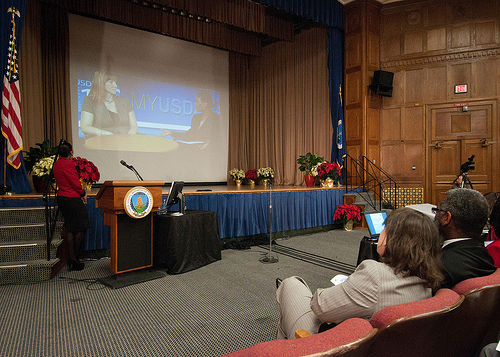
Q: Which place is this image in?
A: It is at the stage.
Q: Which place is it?
A: It is a stage.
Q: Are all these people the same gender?
A: No, they are both male and female.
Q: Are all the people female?
A: No, they are both male and female.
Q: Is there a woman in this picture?
A: Yes, there is a woman.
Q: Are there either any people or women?
A: Yes, there is a woman.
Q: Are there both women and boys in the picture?
A: No, there is a woman but no boys.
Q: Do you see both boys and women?
A: No, there is a woman but no boys.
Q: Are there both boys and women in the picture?
A: No, there is a woman but no boys.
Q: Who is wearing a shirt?
A: The woman is wearing a shirt.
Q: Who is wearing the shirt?
A: The woman is wearing a shirt.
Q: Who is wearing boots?
A: The woman is wearing boots.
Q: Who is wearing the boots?
A: The woman is wearing boots.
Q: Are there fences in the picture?
A: No, there are no fences.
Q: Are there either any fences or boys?
A: No, there are no fences or boys.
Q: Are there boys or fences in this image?
A: No, there are no fences or boys.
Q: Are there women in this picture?
A: Yes, there is a woman.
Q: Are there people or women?
A: Yes, there is a woman.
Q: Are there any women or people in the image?
A: Yes, there is a woman.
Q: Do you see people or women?
A: Yes, there is a woman.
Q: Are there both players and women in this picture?
A: No, there is a woman but no players.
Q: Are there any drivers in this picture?
A: No, there are no drivers.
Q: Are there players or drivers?
A: No, there are no drivers or players.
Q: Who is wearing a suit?
A: The woman is wearing a suit.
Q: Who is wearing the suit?
A: The woman is wearing a suit.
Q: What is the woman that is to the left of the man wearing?
A: The woman is wearing a suit.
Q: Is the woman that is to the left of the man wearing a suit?
A: Yes, the woman is wearing a suit.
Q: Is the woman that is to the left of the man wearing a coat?
A: No, the woman is wearing a suit.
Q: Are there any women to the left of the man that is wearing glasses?
A: Yes, there is a woman to the left of the man.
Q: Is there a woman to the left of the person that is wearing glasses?
A: Yes, there is a woman to the left of the man.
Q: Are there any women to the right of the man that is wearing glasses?
A: No, the woman is to the left of the man.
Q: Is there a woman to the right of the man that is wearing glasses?
A: No, the woman is to the left of the man.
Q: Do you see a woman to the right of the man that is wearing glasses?
A: No, the woman is to the left of the man.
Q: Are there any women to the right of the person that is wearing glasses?
A: No, the woman is to the left of the man.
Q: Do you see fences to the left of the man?
A: No, there is a woman to the left of the man.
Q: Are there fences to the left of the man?
A: No, there is a woman to the left of the man.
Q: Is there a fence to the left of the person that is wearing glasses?
A: No, there is a woman to the left of the man.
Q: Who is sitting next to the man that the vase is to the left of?
A: The woman is sitting next to the man.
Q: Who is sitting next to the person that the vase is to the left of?
A: The woman is sitting next to the man.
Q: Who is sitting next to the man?
A: The woman is sitting next to the man.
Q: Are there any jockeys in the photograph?
A: No, there are no jockeys.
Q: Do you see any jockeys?
A: No, there are no jockeys.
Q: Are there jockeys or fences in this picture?
A: No, there are no jockeys or fences.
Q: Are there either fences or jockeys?
A: No, there are no jockeys or fences.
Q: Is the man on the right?
A: Yes, the man is on the right of the image.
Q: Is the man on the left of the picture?
A: No, the man is on the right of the image.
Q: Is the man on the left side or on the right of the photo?
A: The man is on the right of the image.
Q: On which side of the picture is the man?
A: The man is on the right of the image.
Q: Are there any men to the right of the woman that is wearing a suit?
A: Yes, there is a man to the right of the woman.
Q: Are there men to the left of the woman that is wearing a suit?
A: No, the man is to the right of the woman.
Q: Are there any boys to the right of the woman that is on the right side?
A: No, there is a man to the right of the woman.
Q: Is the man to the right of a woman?
A: Yes, the man is to the right of a woman.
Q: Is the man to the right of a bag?
A: No, the man is to the right of a woman.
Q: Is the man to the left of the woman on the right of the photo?
A: No, the man is to the right of the woman.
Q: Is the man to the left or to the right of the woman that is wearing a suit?
A: The man is to the right of the woman.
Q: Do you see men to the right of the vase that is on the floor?
A: Yes, there is a man to the right of the vase.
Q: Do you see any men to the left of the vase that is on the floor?
A: No, the man is to the right of the vase.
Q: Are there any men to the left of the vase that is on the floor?
A: No, the man is to the right of the vase.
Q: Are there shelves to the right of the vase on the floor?
A: No, there is a man to the right of the vase.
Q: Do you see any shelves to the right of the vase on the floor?
A: No, there is a man to the right of the vase.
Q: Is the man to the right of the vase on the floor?
A: Yes, the man is to the right of the vase.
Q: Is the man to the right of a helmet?
A: No, the man is to the right of the vase.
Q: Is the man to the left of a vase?
A: No, the man is to the right of a vase.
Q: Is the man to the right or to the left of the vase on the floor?
A: The man is to the right of the vase.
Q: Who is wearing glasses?
A: The man is wearing glasses.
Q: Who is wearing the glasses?
A: The man is wearing glasses.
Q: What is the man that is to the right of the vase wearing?
A: The man is wearing glasses.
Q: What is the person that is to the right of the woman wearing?
A: The man is wearing glasses.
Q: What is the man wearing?
A: The man is wearing glasses.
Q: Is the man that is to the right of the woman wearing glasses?
A: Yes, the man is wearing glasses.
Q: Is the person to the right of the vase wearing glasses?
A: Yes, the man is wearing glasses.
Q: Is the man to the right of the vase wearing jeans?
A: No, the man is wearing glasses.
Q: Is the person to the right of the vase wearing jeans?
A: No, the man is wearing glasses.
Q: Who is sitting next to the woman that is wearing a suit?
A: The man is sitting next to the woman.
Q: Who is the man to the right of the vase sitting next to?
A: The man is sitting next to the woman.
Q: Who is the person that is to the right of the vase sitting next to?
A: The man is sitting next to the woman.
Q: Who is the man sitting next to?
A: The man is sitting next to the woman.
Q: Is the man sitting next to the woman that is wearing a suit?
A: Yes, the man is sitting next to the woman.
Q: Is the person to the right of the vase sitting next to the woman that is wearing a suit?
A: Yes, the man is sitting next to the woman.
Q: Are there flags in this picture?
A: Yes, there is a flag.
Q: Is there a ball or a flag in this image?
A: Yes, there is a flag.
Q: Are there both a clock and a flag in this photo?
A: No, there is a flag but no clocks.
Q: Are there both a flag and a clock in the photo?
A: No, there is a flag but no clocks.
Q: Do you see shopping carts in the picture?
A: No, there are no shopping carts.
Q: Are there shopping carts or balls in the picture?
A: No, there are no shopping carts or balls.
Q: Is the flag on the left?
A: Yes, the flag is on the left of the image.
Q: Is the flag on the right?
A: No, the flag is on the left of the image.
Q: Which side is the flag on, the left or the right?
A: The flag is on the left of the image.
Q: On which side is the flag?
A: The flag is on the left of the image.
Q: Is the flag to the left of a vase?
A: Yes, the flag is to the left of a vase.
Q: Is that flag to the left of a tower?
A: No, the flag is to the left of a vase.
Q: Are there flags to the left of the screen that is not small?
A: Yes, there is a flag to the left of the screen.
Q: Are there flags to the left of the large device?
A: Yes, there is a flag to the left of the screen.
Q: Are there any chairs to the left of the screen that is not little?
A: No, there is a flag to the left of the screen.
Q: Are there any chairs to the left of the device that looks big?
A: No, there is a flag to the left of the screen.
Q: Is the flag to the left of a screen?
A: Yes, the flag is to the left of a screen.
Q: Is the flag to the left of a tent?
A: No, the flag is to the left of a screen.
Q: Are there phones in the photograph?
A: No, there are no phones.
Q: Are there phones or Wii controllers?
A: No, there are no phones or Wii controllers.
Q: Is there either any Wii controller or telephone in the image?
A: No, there are no phones or Wii controllers.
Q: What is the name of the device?
A: The device is a screen.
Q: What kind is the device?
A: The device is a screen.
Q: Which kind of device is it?
A: The device is a screen.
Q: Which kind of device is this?
A: This is a screen.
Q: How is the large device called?
A: The device is a screen.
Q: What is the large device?
A: The device is a screen.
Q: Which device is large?
A: The device is a screen.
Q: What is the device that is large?
A: The device is a screen.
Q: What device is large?
A: The device is a screen.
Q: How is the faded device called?
A: The device is a screen.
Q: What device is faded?
A: The device is a screen.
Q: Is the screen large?
A: Yes, the screen is large.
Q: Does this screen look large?
A: Yes, the screen is large.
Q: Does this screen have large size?
A: Yes, the screen is large.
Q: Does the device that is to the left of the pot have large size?
A: Yes, the screen is large.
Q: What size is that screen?
A: The screen is large.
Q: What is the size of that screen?
A: The screen is large.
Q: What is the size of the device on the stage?
A: The screen is large.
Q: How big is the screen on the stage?
A: The screen is large.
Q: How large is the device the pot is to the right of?
A: The screen is large.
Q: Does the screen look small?
A: No, the screen is large.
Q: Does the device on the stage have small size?
A: No, the screen is large.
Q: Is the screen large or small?
A: The screen is large.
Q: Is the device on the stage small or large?
A: The screen is large.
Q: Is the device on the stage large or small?
A: The screen is large.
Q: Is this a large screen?
A: Yes, this is a large screen.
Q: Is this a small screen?
A: No, this is a large screen.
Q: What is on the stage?
A: The screen is on the stage.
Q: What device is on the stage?
A: The device is a screen.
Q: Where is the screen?
A: The screen is on the stage.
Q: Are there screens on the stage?
A: Yes, there is a screen on the stage.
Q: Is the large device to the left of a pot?
A: Yes, the screen is to the left of a pot.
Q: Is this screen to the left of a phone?
A: No, the screen is to the left of a pot.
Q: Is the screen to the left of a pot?
A: Yes, the screen is to the left of a pot.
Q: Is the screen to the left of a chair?
A: No, the screen is to the left of a pot.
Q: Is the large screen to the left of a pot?
A: Yes, the screen is to the left of a pot.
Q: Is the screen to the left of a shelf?
A: No, the screen is to the left of a pot.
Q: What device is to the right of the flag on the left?
A: The device is a screen.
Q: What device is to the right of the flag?
A: The device is a screen.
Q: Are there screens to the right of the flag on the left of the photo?
A: Yes, there is a screen to the right of the flag.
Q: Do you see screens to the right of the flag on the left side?
A: Yes, there is a screen to the right of the flag.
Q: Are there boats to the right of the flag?
A: No, there is a screen to the right of the flag.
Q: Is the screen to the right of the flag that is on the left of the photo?
A: Yes, the screen is to the right of the flag.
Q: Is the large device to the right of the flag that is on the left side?
A: Yes, the screen is to the right of the flag.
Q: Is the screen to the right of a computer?
A: No, the screen is to the right of the flag.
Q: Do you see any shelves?
A: No, there are no shelves.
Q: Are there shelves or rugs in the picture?
A: No, there are no shelves or rugs.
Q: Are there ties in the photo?
A: No, there are no ties.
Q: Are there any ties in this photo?
A: No, there are no ties.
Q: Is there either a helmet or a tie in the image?
A: No, there are no ties or helmets.